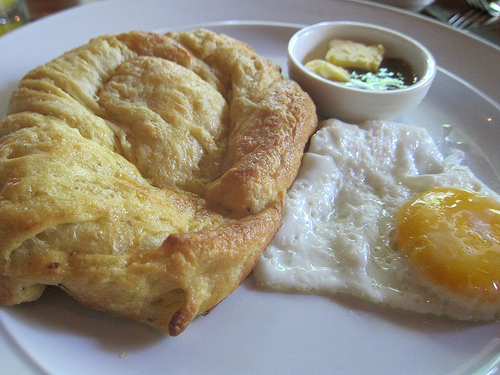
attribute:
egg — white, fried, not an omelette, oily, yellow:
[252, 116, 496, 324]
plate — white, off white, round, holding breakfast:
[5, 6, 496, 370]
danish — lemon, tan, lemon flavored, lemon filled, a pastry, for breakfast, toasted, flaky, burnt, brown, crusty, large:
[5, 29, 319, 336]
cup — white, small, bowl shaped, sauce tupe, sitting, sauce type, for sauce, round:
[288, 21, 436, 124]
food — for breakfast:
[7, 20, 496, 335]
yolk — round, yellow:
[389, 188, 495, 302]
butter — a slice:
[328, 35, 385, 73]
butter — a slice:
[301, 58, 354, 85]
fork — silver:
[446, 2, 496, 34]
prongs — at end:
[446, 5, 492, 32]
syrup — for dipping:
[342, 54, 418, 92]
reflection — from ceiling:
[487, 114, 491, 125]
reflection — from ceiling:
[464, 342, 496, 369]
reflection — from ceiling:
[222, 20, 250, 30]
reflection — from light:
[347, 66, 417, 90]